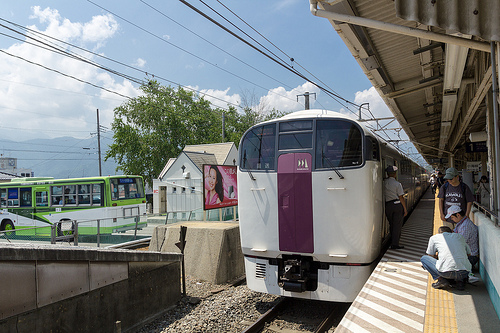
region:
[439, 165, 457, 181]
Baseball hat on man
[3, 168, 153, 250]
Green and white city transit bus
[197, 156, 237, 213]
Wooden billboard with advertising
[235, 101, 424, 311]
Electric train parked at station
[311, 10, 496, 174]
Protective overhang of train platform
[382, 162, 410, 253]
Train driver checking length of train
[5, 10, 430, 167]
Electric power lines for train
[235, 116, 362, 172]
Windshield of train engine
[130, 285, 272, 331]
Gravel covering between train rails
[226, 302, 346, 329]
Metal train rails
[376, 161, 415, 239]
he's leaning on the train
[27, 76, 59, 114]
the clouds are fluffy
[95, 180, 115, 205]
the bus is lime green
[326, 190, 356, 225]
the train is white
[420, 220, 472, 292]
he is bending down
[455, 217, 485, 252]
he is leaning on the wall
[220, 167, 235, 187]
the sign is pink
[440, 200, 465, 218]
the hat is white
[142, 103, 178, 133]
the tree has leaves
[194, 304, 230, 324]
the gravel is gray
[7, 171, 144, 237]
green and white bus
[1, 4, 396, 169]
white clouds in the blue sky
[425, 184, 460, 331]
yellow stripe painted on the train platform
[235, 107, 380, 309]
white train stopped at the station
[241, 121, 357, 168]
front windows of white train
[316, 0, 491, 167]
shelter of train platform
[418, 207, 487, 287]
two men kneeling down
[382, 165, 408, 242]
man standing next to train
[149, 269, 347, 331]
gravel around the train tracks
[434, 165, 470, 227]
man wearing green hat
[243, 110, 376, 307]
front of white and red train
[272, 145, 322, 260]
red door on train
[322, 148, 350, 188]
window wiper on window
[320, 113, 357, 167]
front window of train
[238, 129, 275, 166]
front window of train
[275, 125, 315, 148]
top window on train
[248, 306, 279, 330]
metal train track on ground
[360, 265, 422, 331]
red and white train platform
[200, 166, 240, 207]
red sign by train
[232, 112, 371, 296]
white and red front of train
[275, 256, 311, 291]
black metal connector on front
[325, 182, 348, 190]
white handle bar on front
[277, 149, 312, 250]
purple door on front of train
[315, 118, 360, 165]
front window on train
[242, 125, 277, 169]
front window on train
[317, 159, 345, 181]
black window wiper on front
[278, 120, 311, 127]
numbers on top of train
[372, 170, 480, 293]
people standing on train terminal